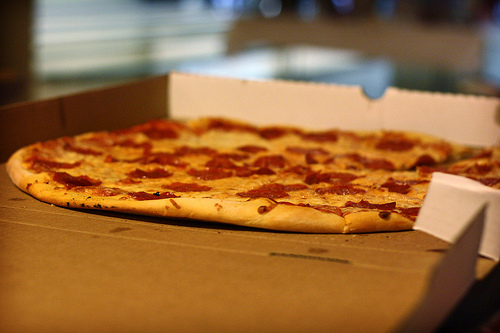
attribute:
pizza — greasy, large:
[3, 114, 500, 232]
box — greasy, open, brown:
[1, 70, 498, 331]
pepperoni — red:
[55, 132, 450, 203]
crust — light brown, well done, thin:
[3, 141, 421, 233]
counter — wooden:
[438, 261, 499, 332]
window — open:
[25, 0, 395, 99]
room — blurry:
[1, 0, 500, 108]